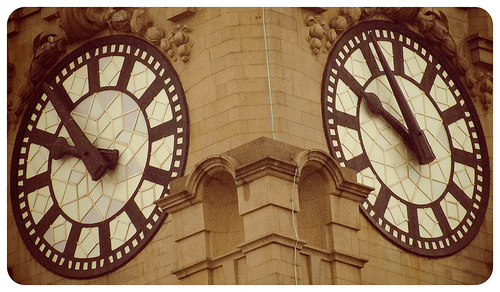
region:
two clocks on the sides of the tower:
[8, 18, 490, 279]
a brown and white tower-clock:
[320, 18, 490, 258]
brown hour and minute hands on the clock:
[357, 30, 434, 165]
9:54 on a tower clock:
[8, 32, 190, 279]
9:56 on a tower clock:
[319, 18, 491, 258]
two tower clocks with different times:
[7, 18, 489, 279]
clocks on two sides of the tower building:
[9, 20, 491, 271]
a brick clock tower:
[9, 20, 491, 277]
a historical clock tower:
[10, 18, 490, 278]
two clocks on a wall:
[10, 19, 487, 279]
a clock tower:
[6, 0, 490, 284]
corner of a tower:
[211, 4, 298, 283]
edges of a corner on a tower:
[152, 135, 376, 276]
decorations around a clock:
[9, 7, 191, 130]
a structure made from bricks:
[5, 8, 489, 285]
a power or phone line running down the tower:
[259, 0, 301, 285]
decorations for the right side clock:
[305, 1, 490, 109]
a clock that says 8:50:
[10, 34, 192, 279]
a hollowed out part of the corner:
[200, 148, 337, 259]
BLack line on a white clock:
[107, 38, 145, 91]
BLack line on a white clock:
[137, 77, 189, 109]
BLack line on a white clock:
[143, 122, 203, 155]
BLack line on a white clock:
[133, 158, 178, 192]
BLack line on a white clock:
[113, 195, 160, 245]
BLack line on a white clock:
[86, 209, 122, 269]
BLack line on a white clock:
[55, 208, 93, 262]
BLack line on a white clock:
[26, 197, 66, 251]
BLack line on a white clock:
[12, 169, 64, 194]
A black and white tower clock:
[322, 28, 496, 276]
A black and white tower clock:
[22, 40, 191, 272]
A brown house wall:
[338, 215, 403, 277]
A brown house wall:
[140, 242, 200, 277]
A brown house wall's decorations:
[113, 13, 184, 45]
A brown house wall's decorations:
[8, 19, 86, 53]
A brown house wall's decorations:
[413, 13, 493, 77]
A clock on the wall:
[42, 86, 154, 230]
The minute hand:
[77, 139, 86, 149]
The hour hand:
[55, 142, 65, 149]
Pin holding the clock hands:
[81, 149, 86, 154]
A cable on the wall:
[268, 96, 271, 106]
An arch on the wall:
[197, 162, 234, 171]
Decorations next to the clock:
[152, 29, 187, 44]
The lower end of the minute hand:
[87, 160, 104, 170]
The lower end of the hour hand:
[109, 150, 114, 165]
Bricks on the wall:
[210, 42, 240, 82]